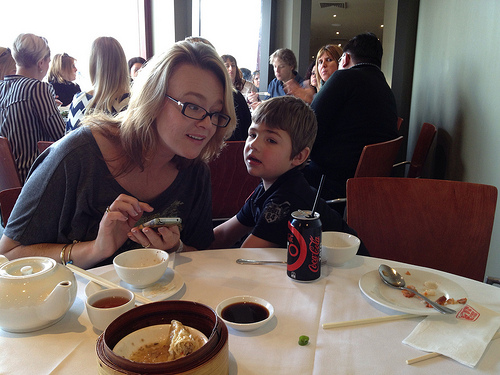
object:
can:
[287, 209, 322, 283]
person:
[0, 41, 238, 272]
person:
[207, 95, 371, 258]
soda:
[285, 209, 320, 282]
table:
[0, 247, 497, 375]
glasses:
[165, 94, 232, 128]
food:
[126, 320, 203, 365]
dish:
[94, 299, 228, 375]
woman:
[310, 44, 343, 92]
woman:
[47, 53, 83, 107]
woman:
[220, 54, 258, 104]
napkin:
[402, 299, 500, 369]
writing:
[456, 304, 480, 322]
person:
[64, 37, 130, 135]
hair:
[76, 41, 236, 181]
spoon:
[377, 264, 456, 316]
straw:
[310, 175, 327, 218]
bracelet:
[60, 240, 82, 267]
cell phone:
[137, 217, 183, 236]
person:
[302, 32, 402, 216]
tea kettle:
[0, 256, 77, 334]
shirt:
[0, 74, 66, 188]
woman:
[0, 33, 67, 186]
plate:
[357, 267, 468, 316]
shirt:
[63, 90, 130, 136]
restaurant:
[0, 0, 500, 375]